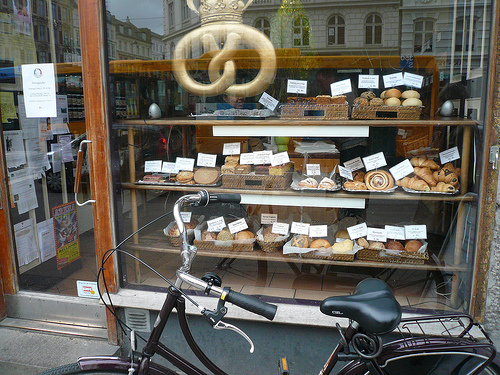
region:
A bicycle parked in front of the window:
[60, 197, 498, 374]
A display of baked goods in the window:
[137, 58, 483, 290]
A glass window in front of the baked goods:
[101, 0, 482, 327]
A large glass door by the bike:
[0, 0, 102, 295]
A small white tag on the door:
[77, 278, 104, 300]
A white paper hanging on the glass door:
[19, 57, 61, 122]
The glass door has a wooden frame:
[73, 0, 123, 298]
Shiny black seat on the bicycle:
[320, 272, 412, 334]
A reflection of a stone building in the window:
[158, 0, 491, 70]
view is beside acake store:
[121, 39, 469, 270]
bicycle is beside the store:
[148, 204, 424, 374]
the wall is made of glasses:
[306, 52, 480, 294]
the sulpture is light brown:
[177, 19, 279, 93]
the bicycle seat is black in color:
[330, 276, 397, 339]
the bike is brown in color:
[414, 306, 497, 366]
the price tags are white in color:
[366, 153, 388, 172]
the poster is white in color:
[7, 52, 67, 122]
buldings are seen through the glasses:
[316, 14, 481, 81]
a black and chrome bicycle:
[27, 185, 498, 372]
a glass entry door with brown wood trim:
[0, 0, 119, 343]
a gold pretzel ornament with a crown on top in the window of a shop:
[169, 0, 279, 101]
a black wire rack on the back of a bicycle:
[365, 308, 495, 353]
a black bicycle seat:
[315, 272, 406, 333]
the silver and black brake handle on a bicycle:
[209, 286, 261, 355]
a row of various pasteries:
[130, 125, 480, 195]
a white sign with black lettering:
[19, 57, 58, 120]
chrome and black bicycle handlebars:
[165, 186, 283, 323]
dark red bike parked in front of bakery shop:
[75, 197, 490, 371]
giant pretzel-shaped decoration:
[172, 19, 273, 96]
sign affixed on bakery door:
[17, 58, 57, 119]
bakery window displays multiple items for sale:
[98, 0, 479, 314]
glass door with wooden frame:
[0, 0, 111, 330]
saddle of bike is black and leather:
[318, 275, 402, 333]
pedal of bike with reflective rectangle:
[275, 354, 292, 374]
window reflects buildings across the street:
[103, 2, 489, 144]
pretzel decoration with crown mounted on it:
[169, 1, 274, 98]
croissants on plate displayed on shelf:
[395, 150, 469, 197]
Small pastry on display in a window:
[401, 236, 421, 255]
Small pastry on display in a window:
[368, 233, 378, 258]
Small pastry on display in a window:
[329, 233, 349, 255]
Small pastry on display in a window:
[305, 226, 333, 261]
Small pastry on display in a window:
[285, 231, 306, 255]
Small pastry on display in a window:
[257, 225, 299, 259]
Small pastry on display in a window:
[229, 227, 269, 254]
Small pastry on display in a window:
[139, 143, 453, 214]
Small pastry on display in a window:
[143, 28, 429, 122]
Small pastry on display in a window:
[362, 164, 393, 197]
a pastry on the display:
[407, 149, 429, 171]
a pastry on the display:
[395, 177, 425, 192]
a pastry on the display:
[397, 227, 425, 257]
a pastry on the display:
[380, 232, 402, 253]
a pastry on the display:
[368, 228, 393, 262]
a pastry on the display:
[328, 236, 352, 261]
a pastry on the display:
[307, 234, 334, 254]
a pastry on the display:
[290, 228, 305, 242]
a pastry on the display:
[257, 222, 272, 240]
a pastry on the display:
[234, 232, 251, 242]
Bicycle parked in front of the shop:
[35, 188, 497, 374]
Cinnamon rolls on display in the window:
[345, 170, 393, 191]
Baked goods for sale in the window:
[142, 88, 462, 253]